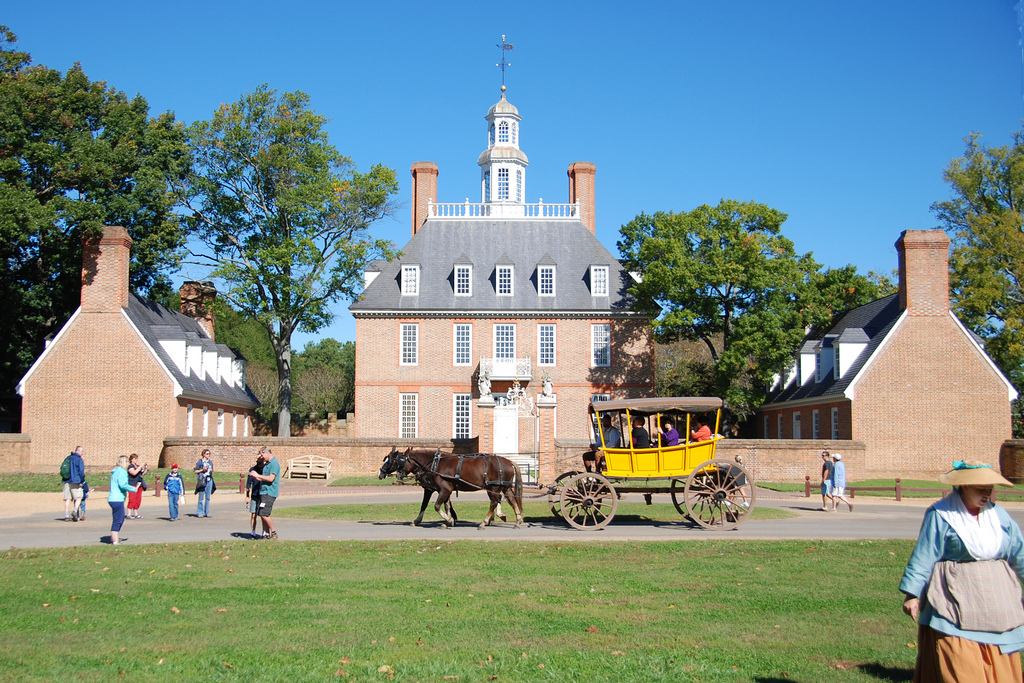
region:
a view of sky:
[659, 66, 802, 174]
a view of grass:
[345, 565, 501, 646]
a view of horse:
[382, 408, 613, 565]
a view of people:
[73, 435, 330, 569]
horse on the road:
[348, 405, 598, 582]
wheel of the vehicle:
[555, 436, 663, 579]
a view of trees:
[629, 181, 867, 397]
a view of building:
[350, 171, 649, 434]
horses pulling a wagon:
[362, 426, 545, 532]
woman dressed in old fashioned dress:
[882, 437, 1022, 679]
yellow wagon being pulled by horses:
[560, 362, 769, 578]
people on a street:
[48, 425, 303, 557]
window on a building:
[385, 306, 438, 372]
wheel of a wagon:
[553, 462, 622, 542]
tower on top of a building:
[459, 14, 540, 212]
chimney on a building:
[874, 217, 969, 304]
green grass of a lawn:
[117, 565, 819, 665]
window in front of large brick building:
[399, 323, 416, 365]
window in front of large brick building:
[452, 323, 471, 365]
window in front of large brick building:
[495, 324, 519, 358]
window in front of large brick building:
[542, 324, 556, 364]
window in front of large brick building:
[592, 320, 611, 367]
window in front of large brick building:
[400, 391, 419, 439]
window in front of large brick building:
[454, 391, 471, 438]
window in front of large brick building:
[399, 263, 423, 295]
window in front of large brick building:
[452, 263, 473, 293]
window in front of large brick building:
[493, 266, 515, 296]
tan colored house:
[341, 152, 630, 422]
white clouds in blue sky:
[572, 19, 626, 65]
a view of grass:
[449, 554, 590, 676]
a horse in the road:
[360, 426, 550, 547]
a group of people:
[66, 411, 307, 596]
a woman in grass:
[874, 446, 1023, 558]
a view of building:
[234, 225, 852, 526]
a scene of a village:
[17, 17, 1017, 653]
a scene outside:
[22, 12, 968, 679]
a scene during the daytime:
[6, 2, 1005, 677]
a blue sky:
[9, 5, 1019, 300]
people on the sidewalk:
[15, 407, 1021, 578]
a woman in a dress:
[864, 432, 1020, 679]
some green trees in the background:
[10, 28, 1013, 456]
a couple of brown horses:
[344, 409, 531, 533]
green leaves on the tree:
[702, 197, 731, 226]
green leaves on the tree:
[681, 291, 757, 425]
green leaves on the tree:
[763, 271, 801, 326]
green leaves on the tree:
[830, 265, 873, 311]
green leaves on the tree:
[675, 180, 713, 320]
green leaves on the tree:
[354, 186, 371, 215]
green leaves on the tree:
[231, 116, 307, 218]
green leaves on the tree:
[122, 133, 200, 232]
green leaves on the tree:
[29, 48, 99, 182]